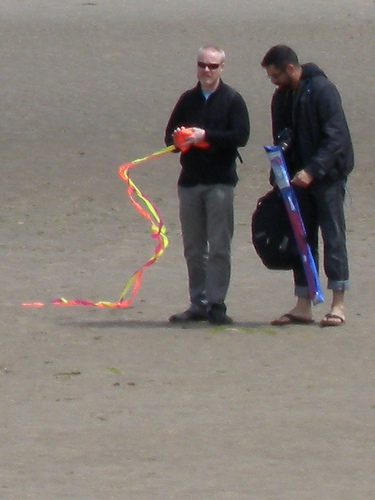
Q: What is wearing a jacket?
A: The man.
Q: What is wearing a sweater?
A: The man.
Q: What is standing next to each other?
A: Two people.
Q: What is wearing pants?
A: The man.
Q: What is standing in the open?
A: Two men.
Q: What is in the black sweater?
A: The man.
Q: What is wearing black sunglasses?
A: The man.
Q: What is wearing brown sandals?
A: The man.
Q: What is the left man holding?
A: Ribbons.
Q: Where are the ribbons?
A: In the left man's hands.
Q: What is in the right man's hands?
A: A blue tube.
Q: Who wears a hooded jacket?
A: The man on the right.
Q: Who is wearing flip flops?
A: The man on the right.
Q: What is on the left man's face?
A: Sunglasses.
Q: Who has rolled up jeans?
A: The man on the right.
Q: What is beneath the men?
A: Dirt.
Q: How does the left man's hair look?
A: Balding.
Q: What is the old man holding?
A: A jump rope.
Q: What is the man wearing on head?
A: Sunglasses.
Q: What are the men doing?
A: Standing in the sand.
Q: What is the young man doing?
A: Looking at the colors.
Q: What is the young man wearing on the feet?
A: Sandals.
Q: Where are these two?
A: On a beach.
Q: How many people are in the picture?
A: Two.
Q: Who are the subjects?
A: Two men.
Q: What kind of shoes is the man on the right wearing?
A: Sandals.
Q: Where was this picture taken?
A: Beach.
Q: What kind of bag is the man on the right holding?
A: Backpack.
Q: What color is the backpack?
A: Black.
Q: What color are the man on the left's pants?
A: Gray.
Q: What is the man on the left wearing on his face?
A: Sunglasses.